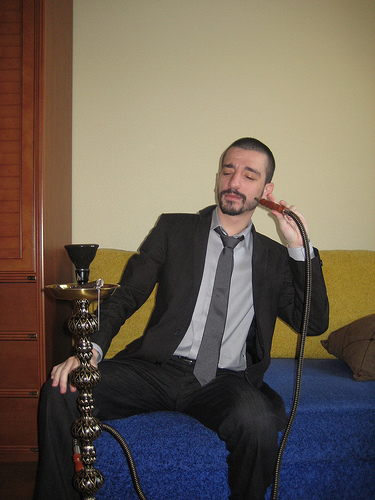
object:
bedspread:
[96, 358, 374, 497]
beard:
[216, 187, 264, 215]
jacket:
[78, 204, 332, 433]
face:
[218, 149, 268, 214]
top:
[65, 243, 99, 281]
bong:
[44, 244, 121, 499]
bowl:
[31, 242, 124, 496]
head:
[215, 136, 274, 215]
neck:
[215, 203, 252, 231]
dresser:
[0, 274, 42, 459]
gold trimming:
[45, 277, 121, 304]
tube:
[258, 193, 315, 499]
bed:
[53, 247, 374, 495]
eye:
[244, 173, 256, 183]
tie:
[192, 225, 248, 387]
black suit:
[36, 205, 330, 500]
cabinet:
[2, 1, 73, 469]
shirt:
[173, 204, 255, 371]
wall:
[71, 0, 374, 240]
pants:
[36, 353, 279, 499]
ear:
[263, 183, 275, 199]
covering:
[94, 356, 374, 498]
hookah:
[42, 240, 152, 499]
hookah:
[247, 181, 289, 221]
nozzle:
[254, 193, 285, 212]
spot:
[322, 476, 333, 482]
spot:
[328, 446, 335, 458]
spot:
[359, 418, 369, 432]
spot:
[318, 392, 327, 396]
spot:
[187, 484, 195, 490]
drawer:
[1, 274, 42, 338]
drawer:
[1, 330, 44, 394]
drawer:
[1, 395, 39, 450]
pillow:
[69, 244, 373, 361]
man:
[37, 137, 333, 499]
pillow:
[318, 313, 374, 380]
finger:
[267, 192, 281, 207]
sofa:
[87, 247, 374, 497]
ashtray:
[41, 280, 122, 300]